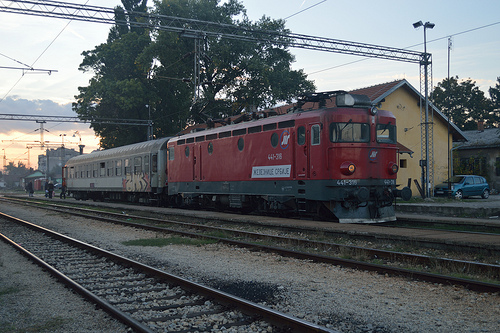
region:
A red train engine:
[162, 99, 412, 225]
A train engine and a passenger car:
[51, 129, 411, 219]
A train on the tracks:
[15, 105, 415, 227]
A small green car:
[411, 167, 491, 199]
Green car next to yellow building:
[432, 127, 487, 201]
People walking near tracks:
[14, 167, 69, 204]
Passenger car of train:
[56, 142, 163, 193]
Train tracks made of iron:
[21, 219, 164, 301]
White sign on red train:
[219, 134, 304, 187]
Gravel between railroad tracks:
[230, 247, 379, 309]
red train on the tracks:
[165, 100, 412, 237]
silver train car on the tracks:
[60, 143, 165, 205]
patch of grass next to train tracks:
[128, 226, 208, 256]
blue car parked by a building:
[437, 161, 489, 202]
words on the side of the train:
[247, 154, 294, 189]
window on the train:
[332, 120, 371, 150]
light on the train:
[342, 160, 359, 180]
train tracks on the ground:
[9, 225, 180, 331]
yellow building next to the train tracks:
[390, 75, 458, 181]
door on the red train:
[289, 122, 311, 179]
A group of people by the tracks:
[26, 180, 68, 198]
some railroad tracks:
[0, 212, 336, 332]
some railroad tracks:
[0, 195, 499, 292]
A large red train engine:
[168, 92, 410, 227]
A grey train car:
[60, 138, 170, 200]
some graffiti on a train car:
[122, 170, 155, 190]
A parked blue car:
[432, 175, 487, 198]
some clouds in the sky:
[1, 93, 98, 133]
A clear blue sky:
[4, 3, 498, 169]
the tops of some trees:
[428, 75, 498, 127]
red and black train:
[161, 107, 401, 207]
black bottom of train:
[159, 173, 374, 201]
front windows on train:
[337, 115, 398, 141]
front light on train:
[338, 161, 361, 173]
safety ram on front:
[332, 186, 404, 222]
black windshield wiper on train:
[335, 115, 354, 134]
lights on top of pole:
[409, 18, 441, 53]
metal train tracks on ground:
[18, 214, 167, 327]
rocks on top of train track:
[70, 243, 165, 316]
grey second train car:
[58, 135, 168, 192]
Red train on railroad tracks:
[163, 101, 403, 206]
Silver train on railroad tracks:
[61, 133, 162, 190]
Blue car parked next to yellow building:
[440, 171, 493, 199]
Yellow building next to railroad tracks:
[346, 70, 467, 202]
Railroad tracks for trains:
[3, 185, 496, 330]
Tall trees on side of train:
[72, 0, 323, 145]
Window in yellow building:
[395, 155, 411, 177]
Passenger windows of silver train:
[62, 147, 154, 177]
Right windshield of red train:
[325, 115, 365, 145]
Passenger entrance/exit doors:
[121, 154, 150, 196]